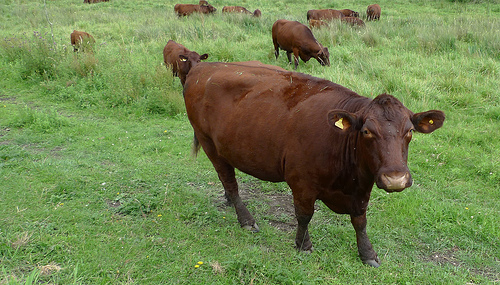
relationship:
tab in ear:
[333, 117, 347, 129] [415, 109, 445, 133]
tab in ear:
[179, 58, 187, 62] [322, 107, 354, 132]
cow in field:
[180, 60, 446, 267] [2, 0, 497, 281]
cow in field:
[272, 19, 332, 70] [2, 0, 497, 281]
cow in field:
[158, 35, 208, 77] [2, 0, 497, 281]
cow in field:
[366, 4, 381, 22] [2, 0, 497, 281]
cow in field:
[70, 30, 95, 52] [2, 0, 497, 281]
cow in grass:
[70, 30, 95, 52] [4, 1, 498, 283]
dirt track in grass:
[1, 134, 61, 159] [4, 1, 498, 283]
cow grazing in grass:
[272, 19, 332, 70] [179, 57, 446, 264]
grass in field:
[179, 57, 446, 264] [2, 0, 497, 281]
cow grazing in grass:
[180, 60, 446, 267] [4, 1, 498, 283]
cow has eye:
[285, 77, 453, 251] [358, 122, 377, 146]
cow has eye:
[285, 77, 453, 251] [398, 122, 420, 142]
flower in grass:
[193, 260, 205, 270] [4, 1, 498, 283]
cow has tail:
[180, 60, 446, 267] [187, 131, 203, 161]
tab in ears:
[335, 117, 344, 130] [327, 110, 357, 136]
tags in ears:
[428, 120, 432, 122] [412, 110, 444, 132]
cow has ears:
[180, 60, 446, 267] [412, 110, 444, 132]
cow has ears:
[180, 60, 446, 267] [327, 110, 357, 136]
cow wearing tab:
[180, 60, 446, 267] [335, 117, 344, 130]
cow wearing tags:
[180, 60, 446, 267] [428, 120, 432, 122]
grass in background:
[381, 12, 498, 75] [3, 4, 496, 61]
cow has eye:
[180, 60, 446, 267] [397, 122, 418, 143]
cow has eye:
[180, 60, 446, 267] [355, 112, 380, 144]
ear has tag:
[324, 108, 361, 135] [335, 116, 345, 128]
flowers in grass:
[0, 99, 499, 281] [24, 83, 162, 219]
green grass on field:
[2, 0, 497, 285] [2, 0, 500, 285]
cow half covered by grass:
[65, 23, 104, 88] [0, 0, 497, 125]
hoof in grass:
[240, 220, 260, 234] [4, 1, 498, 283]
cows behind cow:
[92, 3, 434, 74] [180, 60, 446, 267]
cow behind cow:
[272, 19, 332, 70] [180, 60, 446, 267]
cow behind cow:
[163, 40, 209, 77] [180, 60, 446, 267]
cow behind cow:
[70, 30, 95, 52] [180, 60, 446, 267]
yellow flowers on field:
[194, 259, 204, 269] [2, 0, 500, 285]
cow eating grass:
[266, 16, 332, 67] [4, 1, 498, 283]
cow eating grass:
[361, 2, 387, 23] [4, 1, 498, 283]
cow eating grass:
[167, 0, 213, 17] [4, 1, 498, 283]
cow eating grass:
[219, 5, 265, 21] [4, 1, 498, 283]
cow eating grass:
[70, 30, 95, 52] [4, 1, 498, 283]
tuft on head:
[373, 92, 399, 107] [325, 92, 446, 195]